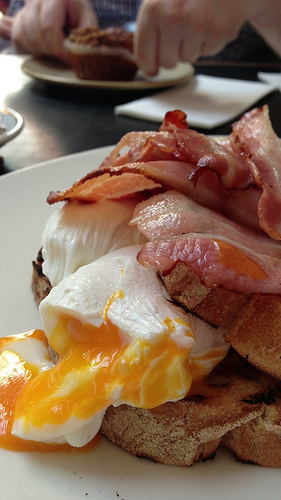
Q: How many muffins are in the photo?
A: One.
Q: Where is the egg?
A: On a plate.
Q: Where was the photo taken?
A: In a restaurant.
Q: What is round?
A: Plates.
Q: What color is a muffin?
A: Brown.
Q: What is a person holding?
A: A muffin.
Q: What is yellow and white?
A: An egg.